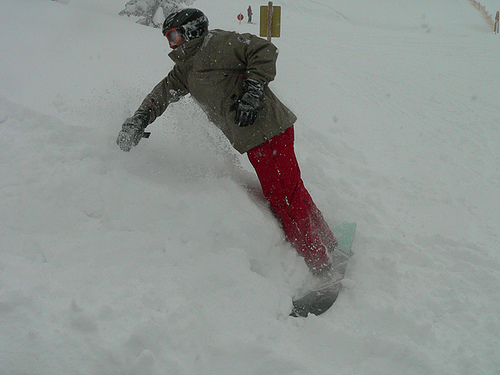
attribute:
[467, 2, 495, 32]
fence — orange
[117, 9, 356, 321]
person — standing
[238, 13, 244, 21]
sign — small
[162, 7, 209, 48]
helmet — black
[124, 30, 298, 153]
jacket — heavy, beige, gray, winter jacket, ski jacket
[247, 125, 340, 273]
pants — red, snow pants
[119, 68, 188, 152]
arm — extended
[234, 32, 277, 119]
arm — bent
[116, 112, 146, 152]
glove — black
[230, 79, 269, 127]
glove — black